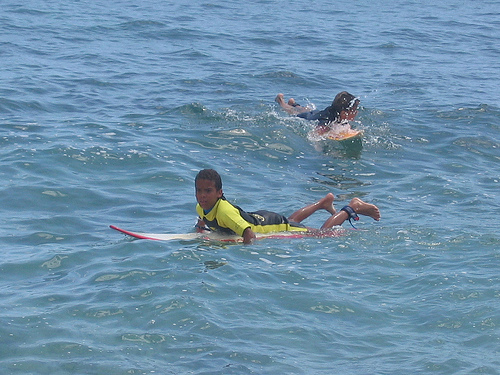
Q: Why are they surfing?
A: Fun.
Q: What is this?
A: Beach.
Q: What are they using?
A: Surfing board.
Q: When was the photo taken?
A: During the day.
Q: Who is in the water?
A: Kids.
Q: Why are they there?
A: They are surfing.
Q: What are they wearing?
A: Wetsuits.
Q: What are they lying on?
A: Surfboards.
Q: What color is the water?
A: Blue.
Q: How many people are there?
A: Two.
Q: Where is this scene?
A: At the beach.